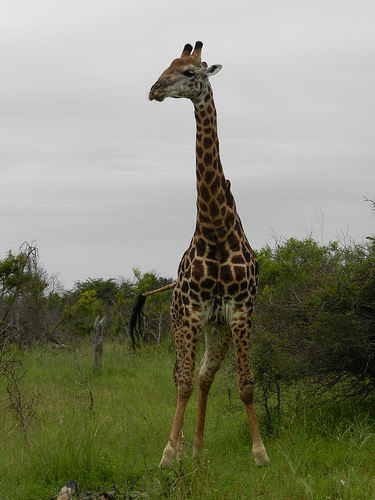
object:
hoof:
[250, 444, 272, 468]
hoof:
[158, 441, 181, 472]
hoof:
[160, 441, 187, 470]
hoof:
[190, 434, 207, 460]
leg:
[186, 324, 228, 467]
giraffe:
[149, 40, 274, 479]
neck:
[190, 78, 246, 240]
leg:
[233, 340, 261, 455]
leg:
[160, 310, 197, 447]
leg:
[171, 299, 189, 461]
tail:
[129, 280, 177, 349]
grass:
[49, 379, 149, 462]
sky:
[0, 0, 375, 289]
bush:
[312, 233, 375, 435]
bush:
[255, 260, 313, 425]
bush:
[71, 291, 100, 343]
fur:
[195, 232, 242, 275]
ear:
[205, 62, 224, 78]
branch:
[17, 395, 27, 403]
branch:
[13, 380, 20, 389]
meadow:
[34, 314, 365, 499]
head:
[148, 39, 222, 103]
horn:
[192, 40, 203, 55]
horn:
[181, 44, 193, 56]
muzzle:
[148, 82, 170, 103]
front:
[187, 248, 252, 314]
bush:
[15, 281, 38, 308]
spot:
[205, 138, 214, 148]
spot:
[208, 110, 210, 113]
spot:
[192, 107, 200, 110]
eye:
[181, 66, 198, 79]